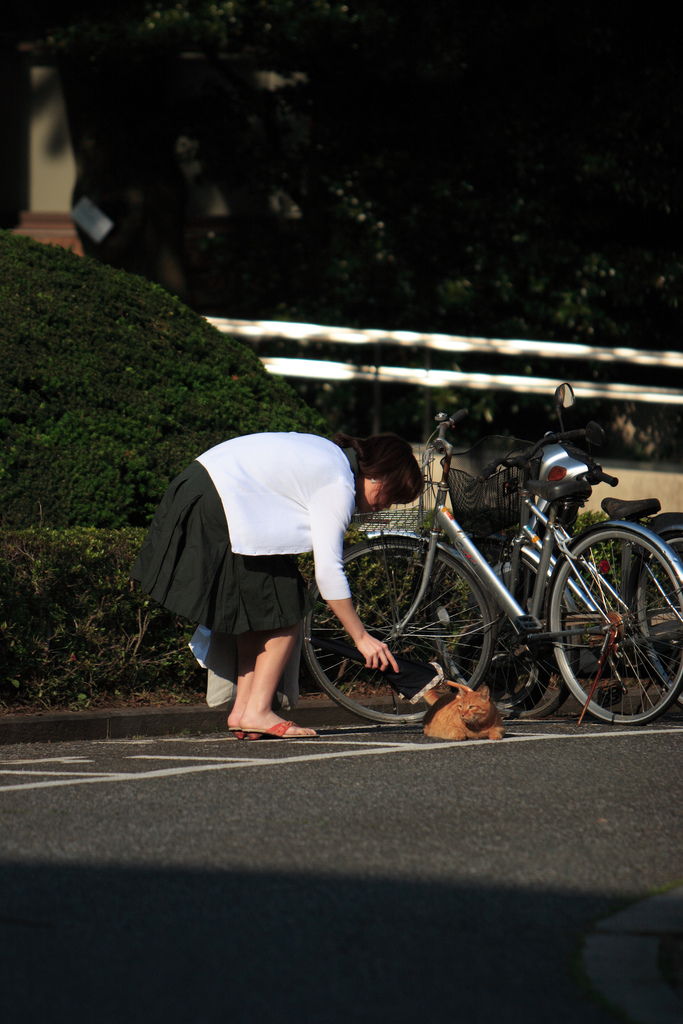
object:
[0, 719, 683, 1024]
ground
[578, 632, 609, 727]
kickstand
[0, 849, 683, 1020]
shadow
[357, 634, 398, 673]
hand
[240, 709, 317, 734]
foot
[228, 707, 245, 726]
foot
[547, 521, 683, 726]
wheel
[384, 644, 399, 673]
finger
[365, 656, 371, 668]
finger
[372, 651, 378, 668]
finger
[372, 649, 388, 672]
finger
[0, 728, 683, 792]
lines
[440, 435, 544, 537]
bag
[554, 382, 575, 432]
mirror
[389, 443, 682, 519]
road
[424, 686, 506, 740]
cat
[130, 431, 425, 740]
woman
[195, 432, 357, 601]
cardigan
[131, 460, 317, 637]
skirt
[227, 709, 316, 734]
feet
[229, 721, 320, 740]
sandals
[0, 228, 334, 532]
bush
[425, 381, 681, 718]
bicycle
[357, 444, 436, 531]
basket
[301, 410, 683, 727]
bicycle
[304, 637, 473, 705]
umbrella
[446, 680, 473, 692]
handle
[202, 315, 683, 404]
fence